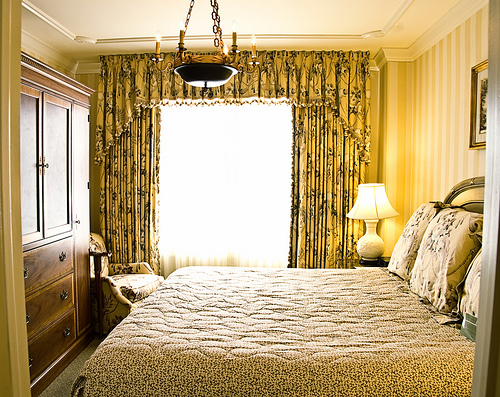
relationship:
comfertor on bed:
[120, 235, 473, 380] [99, 167, 469, 393]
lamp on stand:
[345, 182, 401, 266] [361, 254, 392, 268]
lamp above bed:
[150, 1, 260, 93] [68, 177, 485, 395]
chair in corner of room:
[87, 230, 167, 334] [0, 0, 499, 394]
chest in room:
[18, 50, 90, 393] [0, 0, 499, 394]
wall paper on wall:
[366, 3, 485, 257] [370, 1, 497, 259]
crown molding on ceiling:
[22, 1, 490, 61] [19, 1, 459, 60]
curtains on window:
[93, 52, 370, 270] [155, 101, 293, 278]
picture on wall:
[476, 68, 489, 142] [400, 5, 482, 224]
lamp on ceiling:
[150, 1, 260, 93] [19, 1, 459, 60]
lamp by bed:
[345, 182, 401, 266] [68, 177, 485, 395]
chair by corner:
[89, 232, 165, 333] [20, 42, 150, 343]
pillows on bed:
[386, 198, 483, 331] [68, 177, 485, 395]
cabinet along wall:
[17, 49, 95, 393] [21, 45, 75, 78]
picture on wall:
[470, 60, 487, 148] [403, 3, 486, 220]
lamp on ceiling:
[151, 0, 259, 88] [19, 1, 459, 60]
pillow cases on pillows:
[385, 200, 483, 341] [389, 200, 481, 340]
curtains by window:
[93, 52, 370, 270] [155, 101, 293, 278]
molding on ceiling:
[18, 2, 488, 68] [19, 1, 459, 60]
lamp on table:
[345, 182, 401, 266] [349, 253, 392, 267]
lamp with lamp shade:
[347, 180, 395, 256] [345, 180, 398, 218]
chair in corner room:
[89, 232, 165, 333] [0, 0, 499, 394]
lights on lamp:
[153, 30, 256, 58] [151, 0, 259, 88]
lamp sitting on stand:
[347, 180, 395, 256] [347, 254, 398, 269]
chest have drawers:
[24, 58, 86, 390] [25, 239, 77, 382]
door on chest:
[21, 86, 67, 236] [18, 50, 90, 393]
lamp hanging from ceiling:
[151, 0, 259, 88] [19, 1, 459, 60]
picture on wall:
[476, 68, 489, 142] [370, 1, 497, 259]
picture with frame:
[476, 68, 489, 142] [467, 59, 487, 149]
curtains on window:
[162, 102, 292, 266] [103, 57, 373, 267]